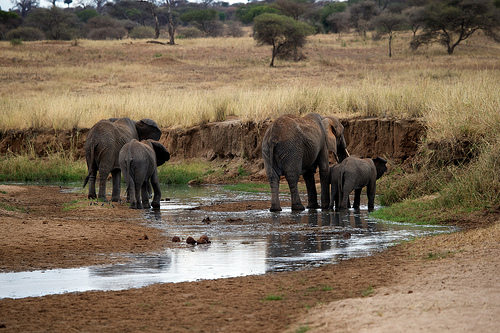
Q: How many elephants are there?
A: 4.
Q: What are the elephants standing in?
A: Water.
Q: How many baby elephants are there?
A: 2.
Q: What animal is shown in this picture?
A: Elephants.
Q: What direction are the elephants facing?
A: Away from the water.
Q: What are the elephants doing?
A: Walking.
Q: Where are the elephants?
A: On the water.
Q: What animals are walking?
A: Elephants.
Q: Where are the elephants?
A: In the watering hole.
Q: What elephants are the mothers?
A: The bigger elephants.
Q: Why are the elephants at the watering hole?
A: To drink and bathe.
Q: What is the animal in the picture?
A: Elephant.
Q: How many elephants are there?
A: 4.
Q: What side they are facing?
A: Backward.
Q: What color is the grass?
A: Green and brown.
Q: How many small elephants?
A: 2.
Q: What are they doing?
A: Walking.